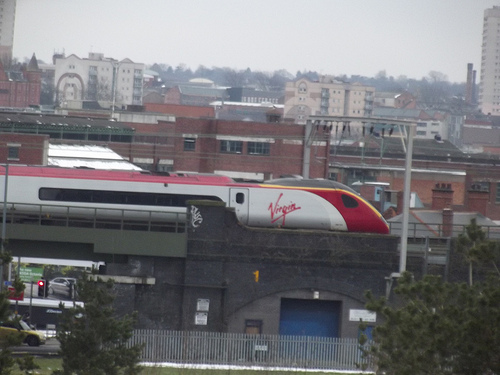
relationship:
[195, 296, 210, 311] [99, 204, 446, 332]
sign on wall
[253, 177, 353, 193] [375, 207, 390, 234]
stripe on nose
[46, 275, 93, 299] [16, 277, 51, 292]
car on road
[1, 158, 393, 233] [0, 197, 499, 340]
train going over bridge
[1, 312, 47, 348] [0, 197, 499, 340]
car driving under bridge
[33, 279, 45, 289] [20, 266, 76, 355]
light hanging above intersection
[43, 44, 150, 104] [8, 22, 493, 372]
building inside of city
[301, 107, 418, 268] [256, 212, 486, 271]
metal scaffolding hanging above tracks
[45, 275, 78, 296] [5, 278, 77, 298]
silver car parked inside of parking lot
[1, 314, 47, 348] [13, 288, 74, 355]
car driving through intersection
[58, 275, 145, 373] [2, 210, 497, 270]
tree underneath track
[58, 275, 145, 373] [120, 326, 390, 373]
tree behind fence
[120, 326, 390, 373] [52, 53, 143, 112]
fence in front of building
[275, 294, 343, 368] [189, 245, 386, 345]
doors on front of building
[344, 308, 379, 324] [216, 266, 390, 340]
sign hanging on building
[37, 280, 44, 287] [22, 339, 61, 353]
light hanging above road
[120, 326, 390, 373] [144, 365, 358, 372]
fence next to sidewalk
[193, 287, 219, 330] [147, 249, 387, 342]
signs hanging on building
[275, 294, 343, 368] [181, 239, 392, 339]
doors on side of building